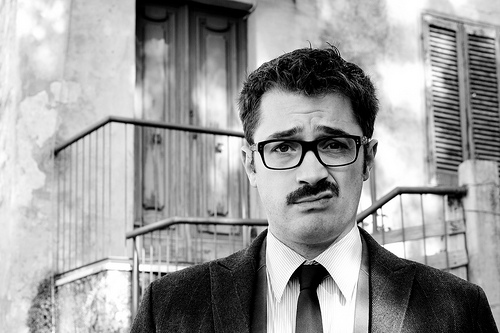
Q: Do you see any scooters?
A: No, there are no scooters.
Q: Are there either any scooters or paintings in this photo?
A: No, there are no scooters or paintings.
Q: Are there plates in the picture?
A: No, there are no plates.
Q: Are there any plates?
A: No, there are no plates.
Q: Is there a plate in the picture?
A: No, there are no plates.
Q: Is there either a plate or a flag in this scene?
A: No, there are no plates or flags.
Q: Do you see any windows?
A: Yes, there is a window.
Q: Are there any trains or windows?
A: Yes, there is a window.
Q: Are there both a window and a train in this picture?
A: No, there is a window but no trains.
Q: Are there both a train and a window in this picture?
A: No, there is a window but no trains.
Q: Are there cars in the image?
A: No, there are no cars.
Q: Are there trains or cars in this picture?
A: No, there are no cars or trains.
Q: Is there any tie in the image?
A: Yes, there is a tie.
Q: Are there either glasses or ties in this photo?
A: Yes, there is a tie.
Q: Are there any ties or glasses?
A: Yes, there is a tie.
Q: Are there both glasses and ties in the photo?
A: Yes, there are both a tie and glasses.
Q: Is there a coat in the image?
A: Yes, there is a coat.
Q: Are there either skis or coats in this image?
A: Yes, there is a coat.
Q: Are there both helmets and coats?
A: No, there is a coat but no helmets.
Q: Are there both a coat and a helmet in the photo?
A: No, there is a coat but no helmets.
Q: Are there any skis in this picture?
A: No, there are no skis.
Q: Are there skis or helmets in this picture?
A: No, there are no skis or helmets.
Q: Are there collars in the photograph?
A: Yes, there is a collar.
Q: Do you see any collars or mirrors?
A: Yes, there is a collar.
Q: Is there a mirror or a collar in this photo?
A: Yes, there is a collar.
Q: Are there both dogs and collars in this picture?
A: No, there is a collar but no dogs.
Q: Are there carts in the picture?
A: No, there are no carts.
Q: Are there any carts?
A: No, there are no carts.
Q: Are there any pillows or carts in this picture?
A: No, there are no carts or pillows.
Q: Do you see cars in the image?
A: No, there are no cars.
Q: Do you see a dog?
A: No, there are no dogs.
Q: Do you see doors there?
A: Yes, there is a door.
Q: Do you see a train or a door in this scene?
A: Yes, there is a door.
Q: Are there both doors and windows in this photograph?
A: Yes, there are both a door and a window.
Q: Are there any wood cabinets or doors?
A: Yes, there is a wood door.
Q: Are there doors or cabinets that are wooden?
A: Yes, the door is wooden.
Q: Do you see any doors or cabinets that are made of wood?
A: Yes, the door is made of wood.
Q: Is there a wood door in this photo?
A: Yes, there is a wood door.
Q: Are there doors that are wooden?
A: Yes, there is a door that is wooden.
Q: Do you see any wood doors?
A: Yes, there is a door that is made of wood.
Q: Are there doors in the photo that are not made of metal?
A: Yes, there is a door that is made of wood.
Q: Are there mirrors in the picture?
A: No, there are no mirrors.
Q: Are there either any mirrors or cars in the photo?
A: No, there are no mirrors or cars.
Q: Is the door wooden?
A: Yes, the door is wooden.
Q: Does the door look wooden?
A: Yes, the door is wooden.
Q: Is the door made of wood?
A: Yes, the door is made of wood.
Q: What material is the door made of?
A: The door is made of wood.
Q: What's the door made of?
A: The door is made of wood.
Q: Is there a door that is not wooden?
A: No, there is a door but it is wooden.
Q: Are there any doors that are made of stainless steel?
A: No, there is a door but it is made of wood.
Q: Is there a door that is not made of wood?
A: No, there is a door but it is made of wood.